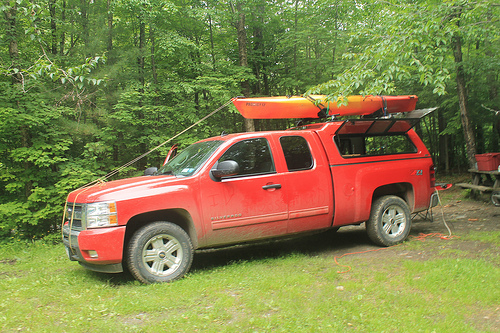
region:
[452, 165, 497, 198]
wooden picnic bench and table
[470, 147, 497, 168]
red plastic bin on picnic table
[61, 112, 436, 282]
large red truck parked on grass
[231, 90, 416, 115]
bright orange canoe on top of truck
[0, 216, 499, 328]
bright green grass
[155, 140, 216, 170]
glass windshield on truck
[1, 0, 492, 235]
woods behind red truck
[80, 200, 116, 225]
white and yellow headlight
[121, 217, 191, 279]
round black rubber tire on truck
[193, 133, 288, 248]
drivers side door of truck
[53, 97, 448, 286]
A RED TRUCK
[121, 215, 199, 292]
FRONT LEFT TIRE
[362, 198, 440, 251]
REAR LEFT TIRE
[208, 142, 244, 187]
A SIDE VIEW MIRROR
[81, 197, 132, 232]
A FRONT HEADLIGHT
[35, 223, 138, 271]
A FRONT FENDER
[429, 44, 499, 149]
A TREE IN THE BACKGROUND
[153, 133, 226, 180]
A FRONT WINDSHIELD OF A TRUCK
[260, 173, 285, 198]
A METAL CAR DOOR HANDLE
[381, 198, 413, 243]
A REAR TIRE HUB CAP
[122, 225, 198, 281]
Front wheel on the red truck.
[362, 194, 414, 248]
Rear wheel on the red truck.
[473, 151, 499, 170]
Red basket on the wooden table.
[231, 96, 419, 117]
Orange canoe on top of the red truck.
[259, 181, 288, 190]
Door handle on the driver side door.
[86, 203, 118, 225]
Front headlight on the red truck.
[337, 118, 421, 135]
Open side window on the red truck.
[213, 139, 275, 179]
Driver side window on the red truck.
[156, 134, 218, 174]
Front windshield window on the red truck.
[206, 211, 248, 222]
Brand name of truck on the driver side door.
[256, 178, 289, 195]
door handle on a vehicle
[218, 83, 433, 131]
orange kayak on a vehicle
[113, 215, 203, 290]
wheel of a vehicle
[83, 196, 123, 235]
front headlight of a vehicle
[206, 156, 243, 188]
side rear view mirror of a vehicle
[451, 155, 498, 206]
picnic table on the ground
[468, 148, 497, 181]
red storage bin on a table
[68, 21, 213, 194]
green trees behind a vehicle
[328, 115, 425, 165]
open side window of a vehicle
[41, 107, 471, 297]
red truck on grass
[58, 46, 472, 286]
red truck in woods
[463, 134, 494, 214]
picnic table beside tree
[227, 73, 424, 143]
orange canoe tied down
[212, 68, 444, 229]
canoe tied on top of truck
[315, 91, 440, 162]
windows open on truck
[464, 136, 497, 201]
red tote on picnic table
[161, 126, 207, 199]
door open on truck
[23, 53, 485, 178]
leafy trees behind truck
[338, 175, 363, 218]
gas tank spout cover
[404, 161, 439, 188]
truck logo painted on fender